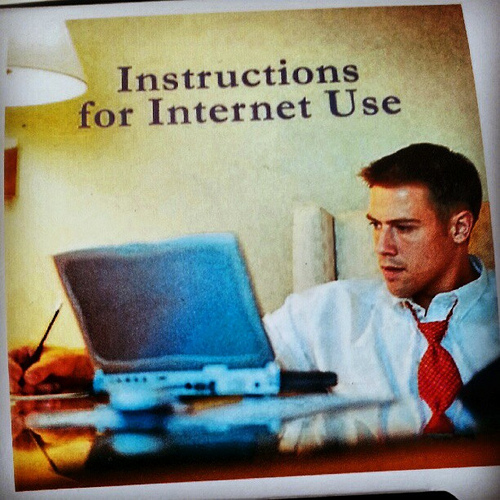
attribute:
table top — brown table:
[8, 380, 499, 499]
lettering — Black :
[196, 69, 212, 91]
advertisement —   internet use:
[11, 8, 485, 478]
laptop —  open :
[45, 235, 345, 413]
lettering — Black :
[239, 66, 263, 88]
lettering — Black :
[260, 64, 276, 87]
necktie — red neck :
[395, 289, 464, 434]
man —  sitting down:
[324, 133, 496, 403]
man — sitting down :
[241, 131, 498, 389]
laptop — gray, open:
[50, 233, 341, 396]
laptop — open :
[34, 218, 289, 421]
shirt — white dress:
[263, 253, 496, 450]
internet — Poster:
[139, 93, 317, 129]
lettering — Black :
[176, 62, 195, 95]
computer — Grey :
[7, 235, 306, 404]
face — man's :
[367, 206, 437, 290]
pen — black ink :
[16, 299, 64, 396]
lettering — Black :
[70, 60, 400, 142]